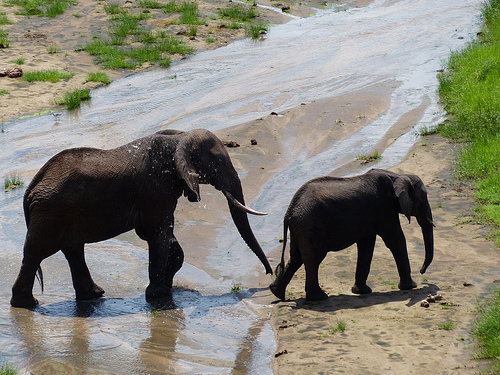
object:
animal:
[272, 167, 432, 311]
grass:
[17, 67, 75, 82]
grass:
[84, 69, 113, 86]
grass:
[54, 87, 94, 109]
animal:
[13, 143, 270, 302]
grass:
[440, 3, 498, 235]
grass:
[113, 28, 194, 77]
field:
[3, 1, 497, 372]